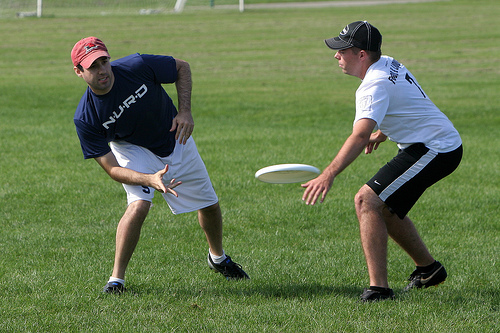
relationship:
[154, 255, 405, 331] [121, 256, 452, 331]
shadow on grass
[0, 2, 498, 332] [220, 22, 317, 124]
field of grass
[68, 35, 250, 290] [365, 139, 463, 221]
man wearing shorts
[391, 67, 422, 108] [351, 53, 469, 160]
number on shirt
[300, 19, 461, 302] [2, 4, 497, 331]
man on grass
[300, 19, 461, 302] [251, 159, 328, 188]
man playing with frisbee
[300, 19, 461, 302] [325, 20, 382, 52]
man wearing baseball hat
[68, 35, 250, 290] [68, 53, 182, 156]
man wearing shirt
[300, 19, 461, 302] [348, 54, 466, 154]
man wearing white shirt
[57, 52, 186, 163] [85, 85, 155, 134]
shirt with letters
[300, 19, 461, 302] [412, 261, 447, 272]
man wearing socks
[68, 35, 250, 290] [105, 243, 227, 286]
man wearing white socks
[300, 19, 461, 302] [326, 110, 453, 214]
man wearing shorts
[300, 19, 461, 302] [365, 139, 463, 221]
man wearing shorts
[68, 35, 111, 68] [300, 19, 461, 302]
hat on man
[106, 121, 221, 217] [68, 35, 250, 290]
white shorts on man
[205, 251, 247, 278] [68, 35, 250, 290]
shoe on man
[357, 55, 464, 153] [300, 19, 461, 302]
shirt on man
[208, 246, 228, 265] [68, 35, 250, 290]
sock on man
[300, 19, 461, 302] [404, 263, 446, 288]
man wearing shoes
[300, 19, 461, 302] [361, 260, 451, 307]
man wearing shoes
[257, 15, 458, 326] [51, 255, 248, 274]
man wearing socks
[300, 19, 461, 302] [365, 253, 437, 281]
man wearing socks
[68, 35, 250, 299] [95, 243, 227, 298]
man wearing socks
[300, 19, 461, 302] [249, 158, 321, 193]
man catching frisbee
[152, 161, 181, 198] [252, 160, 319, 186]
hand throwing frisbee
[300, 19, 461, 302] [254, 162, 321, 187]
man play frisbee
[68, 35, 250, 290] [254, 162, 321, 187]
man play frisbee